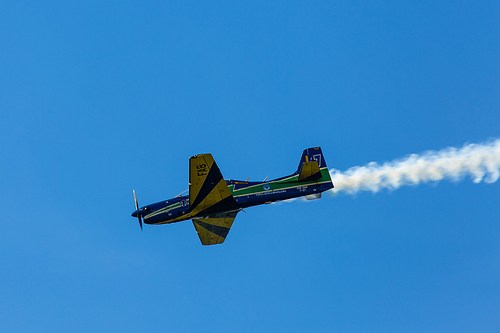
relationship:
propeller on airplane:
[130, 189, 145, 234] [131, 142, 336, 246]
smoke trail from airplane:
[268, 136, 499, 204] [131, 142, 336, 246]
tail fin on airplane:
[296, 146, 327, 173] [131, 142, 336, 246]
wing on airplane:
[187, 152, 236, 210] [131, 142, 336, 246]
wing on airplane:
[192, 209, 239, 245] [131, 142, 336, 246]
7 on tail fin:
[310, 153, 321, 170] [296, 146, 327, 173]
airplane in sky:
[131, 142, 336, 246] [0, 1, 499, 332]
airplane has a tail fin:
[131, 142, 336, 246] [296, 146, 327, 173]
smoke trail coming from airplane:
[268, 136, 499, 204] [131, 142, 336, 246]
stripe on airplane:
[142, 167, 331, 217] [131, 142, 336, 246]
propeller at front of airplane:
[130, 189, 145, 234] [131, 142, 336, 246]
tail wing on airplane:
[298, 160, 323, 184] [131, 142, 336, 246]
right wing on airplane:
[192, 209, 239, 246] [131, 142, 336, 246]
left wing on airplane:
[189, 153, 235, 208] [131, 142, 336, 246]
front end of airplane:
[141, 196, 191, 224] [131, 142, 336, 246]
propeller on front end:
[130, 189, 145, 234] [141, 196, 191, 224]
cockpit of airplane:
[171, 178, 244, 221] [131, 142, 336, 246]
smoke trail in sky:
[268, 136, 499, 204] [0, 1, 499, 332]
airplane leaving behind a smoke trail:
[131, 142, 336, 246] [268, 136, 499, 204]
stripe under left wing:
[145, 158, 240, 243] [187, 153, 235, 208]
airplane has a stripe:
[131, 142, 336, 246] [142, 167, 331, 217]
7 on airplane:
[310, 153, 321, 170] [131, 142, 336, 246]